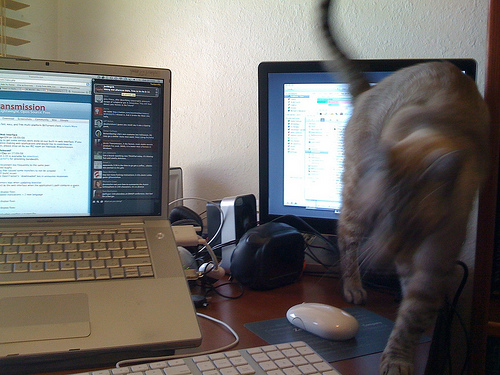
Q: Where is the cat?
A: On the desk.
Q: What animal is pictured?
A: Cat.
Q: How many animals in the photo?
A: 1.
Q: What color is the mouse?
A: White.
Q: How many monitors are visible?
A: 2.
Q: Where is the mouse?
A: On the mouse pad.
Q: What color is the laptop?
A: Silver.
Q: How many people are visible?
A: Zero.